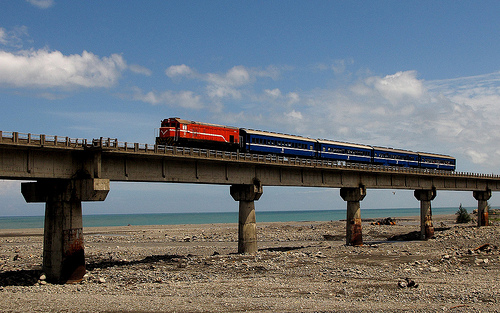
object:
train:
[154, 114, 457, 171]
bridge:
[1, 131, 499, 283]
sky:
[1, 0, 500, 216]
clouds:
[3, 51, 127, 92]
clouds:
[370, 72, 425, 110]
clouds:
[161, 58, 288, 86]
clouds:
[20, 0, 60, 10]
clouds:
[129, 89, 208, 113]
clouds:
[1, 22, 32, 52]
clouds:
[432, 69, 499, 102]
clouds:
[308, 54, 363, 76]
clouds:
[458, 154, 500, 169]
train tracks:
[0, 129, 500, 192]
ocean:
[0, 205, 482, 227]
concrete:
[21, 181, 111, 283]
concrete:
[230, 182, 263, 254]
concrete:
[339, 185, 367, 244]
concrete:
[414, 188, 436, 237]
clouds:
[278, 108, 315, 134]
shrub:
[454, 203, 471, 223]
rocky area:
[0, 223, 500, 309]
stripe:
[0, 130, 493, 178]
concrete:
[473, 190, 492, 226]